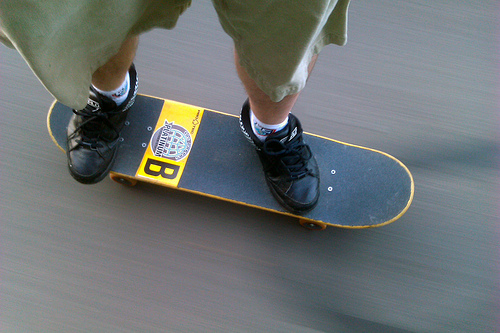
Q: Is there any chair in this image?
A: No, there are no chairs.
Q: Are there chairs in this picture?
A: No, there are no chairs.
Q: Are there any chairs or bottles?
A: No, there are no chairs or bottles.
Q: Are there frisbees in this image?
A: No, there are no frisbees.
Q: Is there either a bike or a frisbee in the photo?
A: No, there are no frisbees or bikes.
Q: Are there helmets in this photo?
A: No, there are no helmets.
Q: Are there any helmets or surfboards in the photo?
A: No, there are no helmets or surfboards.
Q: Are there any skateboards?
A: Yes, there is a skateboard.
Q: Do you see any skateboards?
A: Yes, there is a skateboard.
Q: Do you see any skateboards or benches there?
A: Yes, there is a skateboard.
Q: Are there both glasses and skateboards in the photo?
A: No, there is a skateboard but no glasses.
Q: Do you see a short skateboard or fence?
A: Yes, there is a short skateboard.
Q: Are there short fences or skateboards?
A: Yes, there is a short skateboard.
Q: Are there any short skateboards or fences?
A: Yes, there is a short skateboard.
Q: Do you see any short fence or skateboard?
A: Yes, there is a short skateboard.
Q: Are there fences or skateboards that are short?
A: Yes, the skateboard is short.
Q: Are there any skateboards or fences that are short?
A: Yes, the skateboard is short.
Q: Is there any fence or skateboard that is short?
A: Yes, the skateboard is short.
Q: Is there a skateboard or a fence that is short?
A: Yes, the skateboard is short.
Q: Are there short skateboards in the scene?
A: Yes, there is a short skateboard.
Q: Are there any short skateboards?
A: Yes, there is a short skateboard.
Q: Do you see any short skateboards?
A: Yes, there is a short skateboard.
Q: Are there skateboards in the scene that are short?
A: Yes, there is a short skateboard.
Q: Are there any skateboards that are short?
A: Yes, there is a skateboard that is short.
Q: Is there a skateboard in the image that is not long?
A: Yes, there is a short skateboard.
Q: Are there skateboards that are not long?
A: Yes, there is a short skateboard.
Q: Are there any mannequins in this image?
A: No, there are no mannequins.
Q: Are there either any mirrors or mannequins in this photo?
A: No, there are no mannequins or mirrors.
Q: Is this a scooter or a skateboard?
A: This is a skateboard.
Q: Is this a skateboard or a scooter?
A: This is a skateboard.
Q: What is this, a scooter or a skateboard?
A: This is a skateboard.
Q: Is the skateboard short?
A: Yes, the skateboard is short.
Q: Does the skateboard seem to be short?
A: Yes, the skateboard is short.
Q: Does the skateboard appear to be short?
A: Yes, the skateboard is short.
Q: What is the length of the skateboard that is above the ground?
A: The skateboard is short.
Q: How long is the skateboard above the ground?
A: The skateboard is short.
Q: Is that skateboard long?
A: No, the skateboard is short.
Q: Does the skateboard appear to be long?
A: No, the skateboard is short.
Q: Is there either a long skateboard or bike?
A: No, there is a skateboard but it is short.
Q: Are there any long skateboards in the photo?
A: No, there is a skateboard but it is short.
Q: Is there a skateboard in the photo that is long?
A: No, there is a skateboard but it is short.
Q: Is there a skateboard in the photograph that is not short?
A: No, there is a skateboard but it is short.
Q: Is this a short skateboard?
A: Yes, this is a short skateboard.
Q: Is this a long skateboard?
A: No, this is a short skateboard.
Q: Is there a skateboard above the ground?
A: Yes, there is a skateboard above the ground.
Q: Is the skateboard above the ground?
A: Yes, the skateboard is above the ground.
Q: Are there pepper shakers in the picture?
A: No, there are no pepper shakers.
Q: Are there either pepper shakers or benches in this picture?
A: No, there are no pepper shakers or benches.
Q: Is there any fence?
A: No, there are no fences.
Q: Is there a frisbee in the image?
A: No, there are no frisbees.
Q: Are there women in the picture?
A: No, there are no women.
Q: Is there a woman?
A: No, there are no women.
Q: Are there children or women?
A: No, there are no women or children.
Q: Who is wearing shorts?
A: The man is wearing shorts.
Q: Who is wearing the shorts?
A: The man is wearing shorts.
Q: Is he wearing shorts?
A: Yes, the man is wearing shorts.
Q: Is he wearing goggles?
A: No, the man is wearing shorts.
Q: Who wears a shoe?
A: The man wears a shoe.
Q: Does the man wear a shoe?
A: Yes, the man wears a shoe.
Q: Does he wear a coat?
A: No, the man wears a shoe.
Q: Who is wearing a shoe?
A: The man is wearing a shoe.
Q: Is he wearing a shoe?
A: Yes, the man is wearing a shoe.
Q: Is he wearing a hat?
A: No, the man is wearing a shoe.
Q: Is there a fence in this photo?
A: No, there are no fences.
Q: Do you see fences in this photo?
A: No, there are no fences.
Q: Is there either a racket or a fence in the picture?
A: No, there are no fences or rackets.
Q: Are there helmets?
A: No, there are no helmets.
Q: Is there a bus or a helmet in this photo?
A: No, there are no helmets or buses.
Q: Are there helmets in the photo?
A: No, there are no helmets.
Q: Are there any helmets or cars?
A: No, there are no helmets or cars.